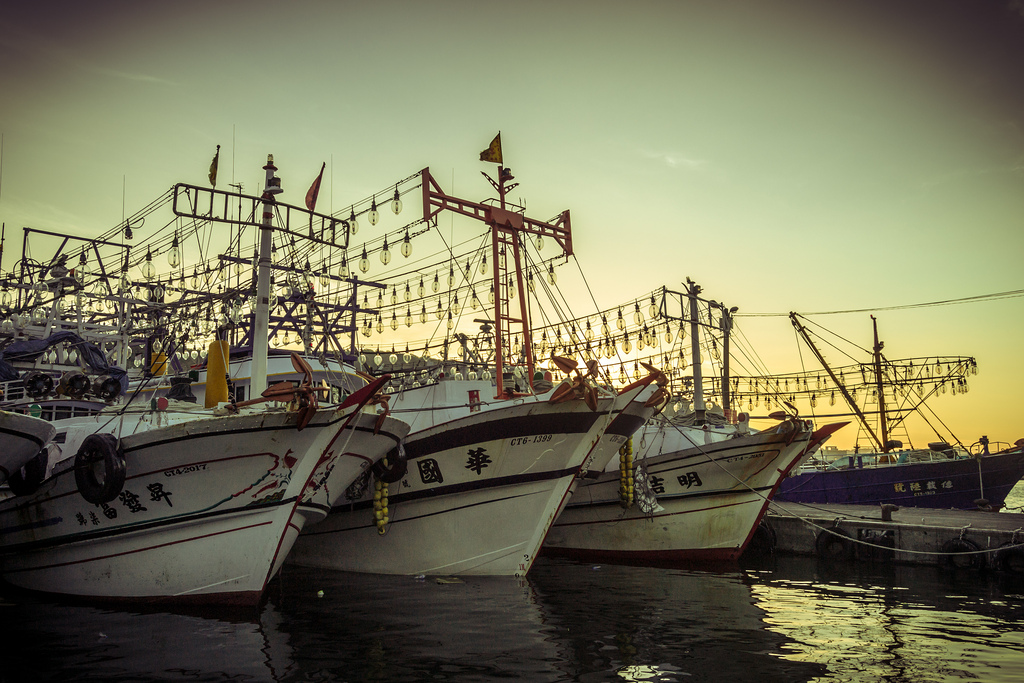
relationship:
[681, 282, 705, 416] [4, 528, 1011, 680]
pole on water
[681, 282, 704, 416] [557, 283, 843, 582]
pole on boat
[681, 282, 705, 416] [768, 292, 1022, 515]
pole on boat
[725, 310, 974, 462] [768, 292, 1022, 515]
cable on boat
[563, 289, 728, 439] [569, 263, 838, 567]
cable on boat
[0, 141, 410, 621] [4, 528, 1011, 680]
boat in water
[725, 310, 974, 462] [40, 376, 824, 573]
cable in boats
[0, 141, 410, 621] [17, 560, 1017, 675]
boat in water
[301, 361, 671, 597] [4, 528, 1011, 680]
boat in water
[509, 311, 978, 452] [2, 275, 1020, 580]
sunset in boats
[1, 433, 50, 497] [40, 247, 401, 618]
tire on boat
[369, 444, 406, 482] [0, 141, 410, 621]
tire on boat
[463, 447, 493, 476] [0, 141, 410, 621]
character on boat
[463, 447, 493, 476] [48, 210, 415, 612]
character on boat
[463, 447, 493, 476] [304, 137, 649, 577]
character on boat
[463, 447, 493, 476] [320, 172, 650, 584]
character on boat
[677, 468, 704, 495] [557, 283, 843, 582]
character on boat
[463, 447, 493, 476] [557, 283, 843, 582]
character on boat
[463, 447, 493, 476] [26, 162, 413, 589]
character on boat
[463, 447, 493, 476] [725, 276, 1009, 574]
character on boat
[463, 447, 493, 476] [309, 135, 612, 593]
character on boat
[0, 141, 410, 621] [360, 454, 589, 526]
boat has stripe